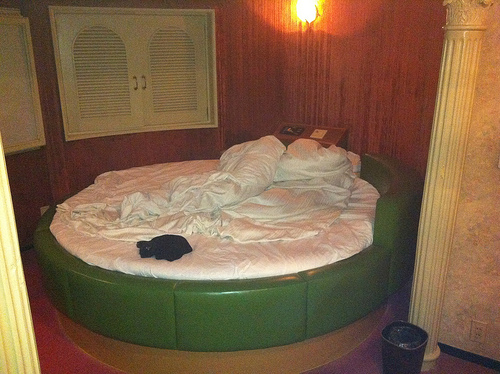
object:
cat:
[133, 233, 192, 261]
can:
[380, 317, 429, 373]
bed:
[35, 121, 418, 373]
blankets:
[49, 137, 382, 283]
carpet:
[21, 249, 125, 373]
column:
[0, 126, 42, 372]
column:
[404, 0, 489, 362]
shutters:
[52, 9, 215, 146]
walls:
[0, 1, 446, 251]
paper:
[425, 2, 499, 363]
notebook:
[310, 127, 328, 140]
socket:
[468, 318, 486, 347]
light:
[294, 1, 321, 28]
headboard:
[361, 149, 423, 250]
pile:
[62, 141, 351, 228]